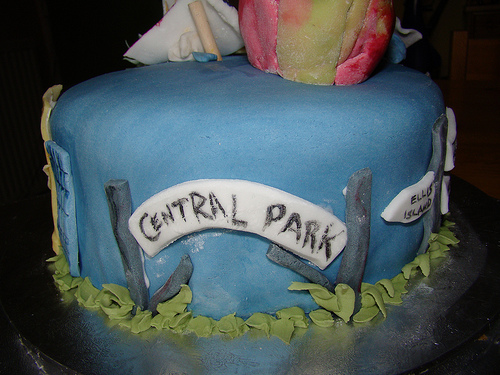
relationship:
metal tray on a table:
[6, 191, 499, 372] [6, 73, 499, 374]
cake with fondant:
[52, 71, 460, 329] [133, 1, 409, 88]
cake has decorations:
[52, 71, 460, 329] [133, 1, 409, 88]